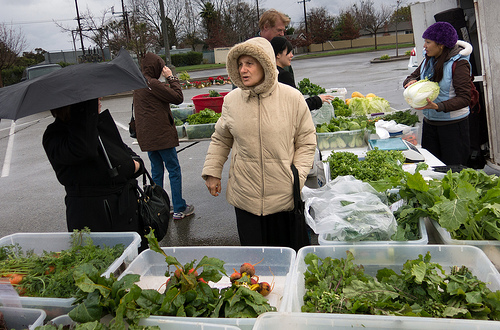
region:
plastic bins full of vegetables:
[0, 200, 484, 311]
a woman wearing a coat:
[202, 24, 284, 179]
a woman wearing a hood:
[210, 27, 274, 102]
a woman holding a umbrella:
[2, 34, 140, 164]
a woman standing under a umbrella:
[8, 36, 164, 153]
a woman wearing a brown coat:
[125, 26, 180, 189]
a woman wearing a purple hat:
[412, 22, 459, 54]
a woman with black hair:
[270, 29, 298, 71]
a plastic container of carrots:
[0, 229, 142, 308]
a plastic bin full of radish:
[167, 248, 275, 322]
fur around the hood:
[219, 39, 276, 97]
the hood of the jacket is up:
[216, 33, 289, 99]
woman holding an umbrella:
[2, 57, 186, 244]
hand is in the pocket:
[283, 160, 310, 201]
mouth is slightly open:
[239, 72, 251, 83]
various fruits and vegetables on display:
[1, 83, 496, 328]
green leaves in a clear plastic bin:
[302, 245, 498, 322]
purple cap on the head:
[416, 20, 466, 51]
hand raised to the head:
[155, 63, 177, 83]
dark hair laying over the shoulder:
[426, 48, 448, 82]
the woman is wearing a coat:
[204, 36, 316, 216]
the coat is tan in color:
[210, 31, 318, 216]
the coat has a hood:
[226, 35, 278, 97]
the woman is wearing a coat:
[128, 55, 183, 150]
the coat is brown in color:
[134, 58, 184, 153]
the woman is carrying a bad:
[130, 88, 140, 140]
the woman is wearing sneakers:
[166, 199, 198, 219]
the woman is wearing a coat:
[42, 114, 141, 227]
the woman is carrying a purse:
[93, 118, 178, 235]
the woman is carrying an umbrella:
[5, 50, 159, 115]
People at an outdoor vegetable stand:
[1, 8, 498, 326]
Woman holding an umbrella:
[0, 54, 161, 229]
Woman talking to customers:
[403, 20, 481, 169]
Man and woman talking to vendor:
[260, 9, 336, 112]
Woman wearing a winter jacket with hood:
[200, 32, 318, 213]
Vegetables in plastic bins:
[2, 229, 496, 326]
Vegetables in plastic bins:
[300, 83, 497, 328]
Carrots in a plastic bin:
[0, 226, 135, 295]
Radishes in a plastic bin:
[108, 243, 292, 315]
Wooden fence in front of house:
[305, 35, 417, 54]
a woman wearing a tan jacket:
[191, 38, 325, 232]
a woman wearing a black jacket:
[41, 112, 188, 236]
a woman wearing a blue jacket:
[404, 29, 485, 143]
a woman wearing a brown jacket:
[122, 65, 186, 156]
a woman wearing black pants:
[221, 195, 298, 246]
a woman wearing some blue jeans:
[138, 146, 203, 224]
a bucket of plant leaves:
[331, 248, 471, 318]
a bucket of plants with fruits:
[142, 242, 277, 313]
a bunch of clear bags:
[322, 159, 386, 231]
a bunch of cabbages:
[342, 85, 389, 123]